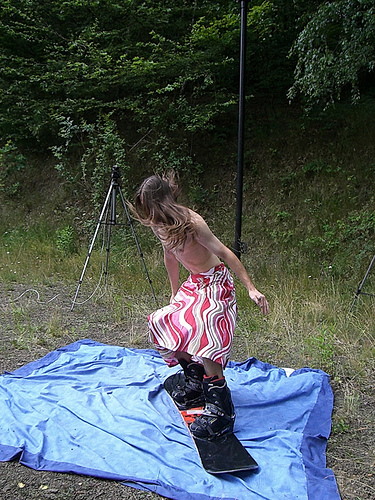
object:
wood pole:
[234, 77, 244, 254]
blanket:
[0, 337, 339, 499]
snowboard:
[165, 374, 260, 475]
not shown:
[0, 2, 372, 495]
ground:
[0, 263, 371, 498]